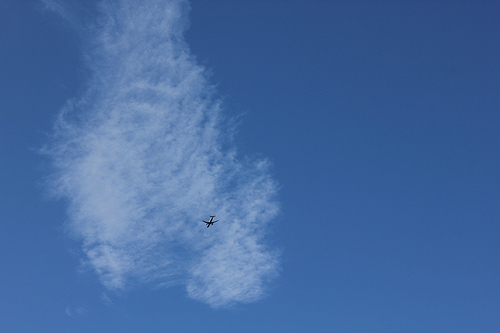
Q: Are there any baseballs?
A: No, there are no baseballs.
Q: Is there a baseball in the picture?
A: No, there are no baseballs.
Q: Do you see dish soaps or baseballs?
A: No, there are no baseballs or dish soaps.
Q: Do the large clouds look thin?
A: Yes, the clouds are thin.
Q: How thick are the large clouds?
A: The clouds are thin.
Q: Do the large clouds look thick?
A: No, the clouds are thin.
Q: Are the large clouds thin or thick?
A: The clouds are thin.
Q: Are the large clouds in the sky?
A: Yes, the clouds are in the sky.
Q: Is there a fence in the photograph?
A: No, there are no fences.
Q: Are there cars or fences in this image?
A: No, there are no fences or cars.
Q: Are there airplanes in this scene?
A: Yes, there is an airplane.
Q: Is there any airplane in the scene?
A: Yes, there is an airplane.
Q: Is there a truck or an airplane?
A: Yes, there is an airplane.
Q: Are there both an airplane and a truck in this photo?
A: No, there is an airplane but no trucks.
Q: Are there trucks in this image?
A: No, there are no trucks.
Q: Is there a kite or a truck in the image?
A: No, there are no trucks or kites.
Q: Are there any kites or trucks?
A: No, there are no trucks or kites.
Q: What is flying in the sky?
A: The plane is flying in the sky.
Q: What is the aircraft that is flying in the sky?
A: The aircraft is an airplane.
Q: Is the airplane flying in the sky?
A: Yes, the airplane is flying in the sky.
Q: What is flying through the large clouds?
A: The plane is flying through the clouds.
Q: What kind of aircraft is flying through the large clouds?
A: The aircraft is an airplane.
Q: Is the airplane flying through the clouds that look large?
A: Yes, the airplane is flying through the clouds.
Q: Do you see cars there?
A: No, there are no cars.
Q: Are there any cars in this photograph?
A: No, there are no cars.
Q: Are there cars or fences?
A: No, there are no cars or fences.